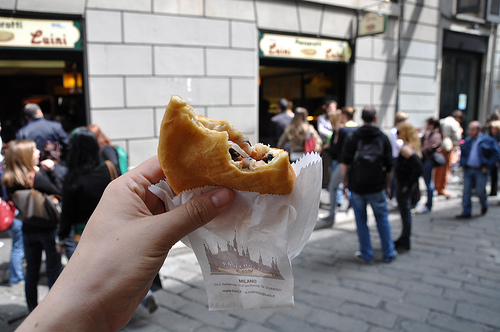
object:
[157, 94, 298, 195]
empanada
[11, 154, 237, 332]
person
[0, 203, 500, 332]
street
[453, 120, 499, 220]
person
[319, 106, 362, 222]
person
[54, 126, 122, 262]
person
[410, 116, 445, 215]
person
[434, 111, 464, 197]
person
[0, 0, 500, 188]
building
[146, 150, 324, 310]
bag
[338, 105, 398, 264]
man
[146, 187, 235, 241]
thumb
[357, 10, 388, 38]
sign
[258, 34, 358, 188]
business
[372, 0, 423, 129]
shadow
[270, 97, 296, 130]
person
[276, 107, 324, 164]
person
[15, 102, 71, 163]
person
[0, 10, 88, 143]
restaurant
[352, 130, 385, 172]
backpack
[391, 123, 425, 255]
woman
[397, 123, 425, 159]
hair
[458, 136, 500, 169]
coat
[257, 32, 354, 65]
sign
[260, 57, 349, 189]
doorway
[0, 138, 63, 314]
girl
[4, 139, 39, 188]
hair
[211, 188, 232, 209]
nail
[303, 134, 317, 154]
bag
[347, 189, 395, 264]
blue jeans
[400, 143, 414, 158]
bare shoulders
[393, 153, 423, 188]
clothing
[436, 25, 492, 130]
door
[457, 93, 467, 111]
sign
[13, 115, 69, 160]
coat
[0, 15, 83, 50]
sign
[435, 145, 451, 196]
pants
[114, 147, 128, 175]
backpack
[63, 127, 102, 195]
hair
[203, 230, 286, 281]
logo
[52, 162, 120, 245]
shirt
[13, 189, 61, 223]
bag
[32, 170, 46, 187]
shoulder